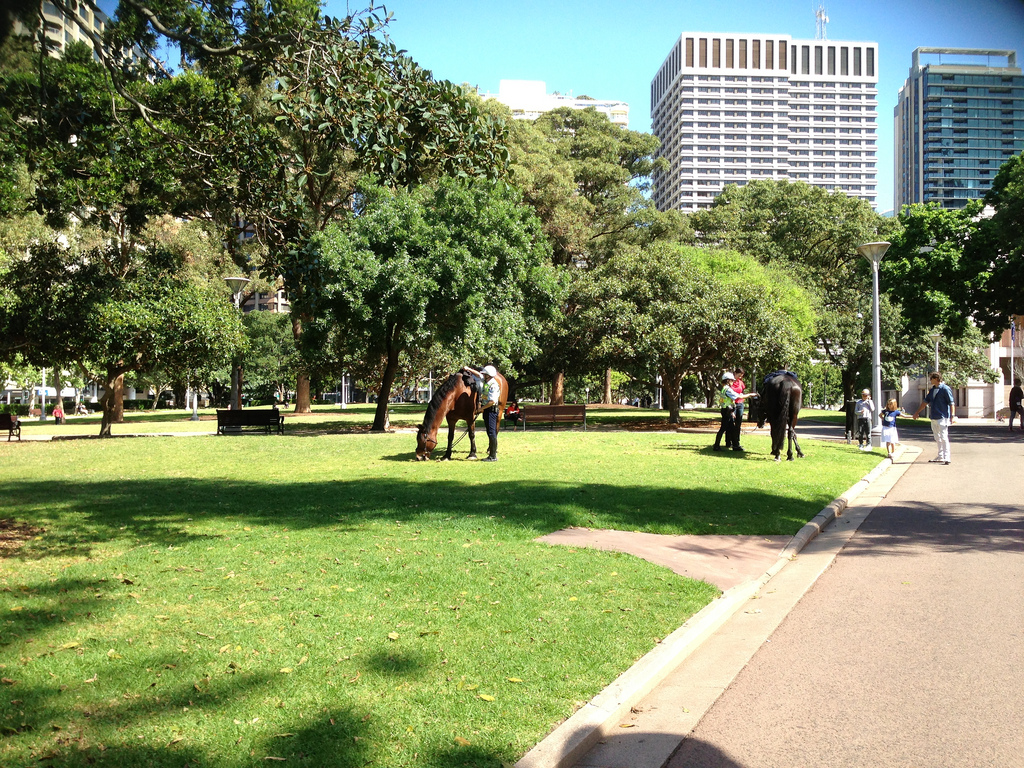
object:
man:
[476, 365, 503, 462]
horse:
[414, 364, 507, 461]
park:
[0, 402, 1024, 768]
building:
[651, 32, 878, 409]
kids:
[854, 388, 874, 448]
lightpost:
[859, 242, 892, 448]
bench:
[216, 408, 285, 436]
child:
[879, 399, 920, 458]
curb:
[512, 421, 1024, 768]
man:
[914, 372, 955, 465]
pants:
[931, 418, 950, 461]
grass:
[0, 403, 892, 768]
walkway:
[504, 415, 1024, 768]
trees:
[0, 0, 1024, 438]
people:
[52, 404, 65, 425]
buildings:
[893, 46, 1024, 418]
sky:
[99, 0, 1024, 221]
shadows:
[0, 477, 1024, 561]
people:
[714, 372, 758, 451]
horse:
[758, 369, 805, 460]